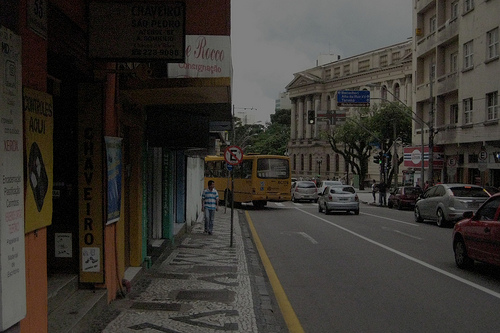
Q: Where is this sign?
A: Front of building.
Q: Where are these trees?
A: On sidewalk.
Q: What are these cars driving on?
A: A street.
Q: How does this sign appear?
A: With black lettering.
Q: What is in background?
A: Tan buildings.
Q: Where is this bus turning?
A: Around corner.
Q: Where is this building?
A: On the right.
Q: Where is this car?
A: On a street.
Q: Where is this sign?
A: On doorway.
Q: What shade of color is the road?
A: Gray.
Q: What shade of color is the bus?
A: Yellow.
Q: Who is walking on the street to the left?
A: A man.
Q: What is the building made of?
A: Stones.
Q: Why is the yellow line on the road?
A: Marking.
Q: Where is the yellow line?
A: Edge of the street.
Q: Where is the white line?
A: Street.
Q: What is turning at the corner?
A: Bus.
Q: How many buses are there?
A: One.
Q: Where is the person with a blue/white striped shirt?
A: Sidewalk.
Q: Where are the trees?
A: Sidewalk.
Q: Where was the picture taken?
A: On a sidewalk.